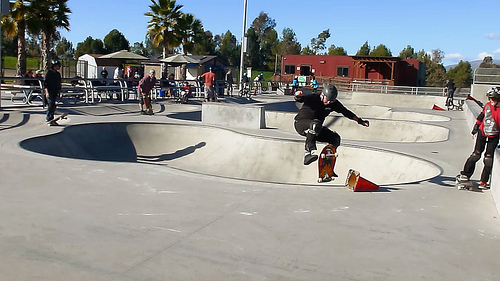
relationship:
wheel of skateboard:
[317, 149, 329, 161] [315, 143, 344, 189]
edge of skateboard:
[43, 110, 76, 126] [43, 110, 71, 130]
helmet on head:
[317, 79, 344, 104] [316, 82, 342, 108]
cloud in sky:
[474, 52, 496, 64] [1, 0, 497, 69]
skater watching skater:
[447, 75, 500, 191] [290, 83, 374, 170]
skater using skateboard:
[290, 83, 374, 170] [315, 143, 344, 189]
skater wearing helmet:
[37, 57, 75, 129] [46, 57, 62, 71]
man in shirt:
[447, 75, 500, 191] [465, 98, 499, 138]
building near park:
[268, 47, 427, 94] [0, 67, 498, 279]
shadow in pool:
[134, 139, 208, 166] [20, 120, 456, 199]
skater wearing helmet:
[447, 75, 500, 191] [485, 85, 500, 103]